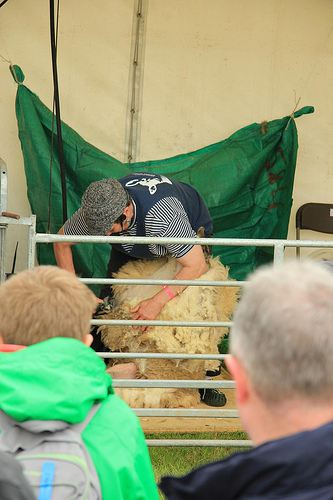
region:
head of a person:
[74, 183, 133, 245]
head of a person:
[195, 268, 331, 435]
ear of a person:
[217, 355, 246, 402]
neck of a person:
[229, 400, 329, 450]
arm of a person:
[139, 239, 203, 328]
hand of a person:
[125, 292, 168, 331]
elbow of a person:
[199, 256, 225, 278]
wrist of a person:
[150, 288, 173, 308]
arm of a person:
[48, 229, 99, 292]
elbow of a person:
[48, 229, 72, 259]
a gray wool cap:
[78, 177, 127, 234]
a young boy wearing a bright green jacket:
[0, 252, 153, 498]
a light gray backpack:
[0, 388, 110, 498]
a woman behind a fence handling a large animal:
[45, 170, 241, 407]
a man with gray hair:
[185, 258, 332, 498]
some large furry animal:
[91, 251, 237, 404]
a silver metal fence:
[0, 241, 330, 347]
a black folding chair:
[297, 201, 331, 256]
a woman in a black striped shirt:
[56, 174, 218, 273]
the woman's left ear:
[120, 208, 134, 216]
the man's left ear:
[218, 353, 249, 403]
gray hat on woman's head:
[80, 175, 127, 238]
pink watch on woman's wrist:
[159, 284, 177, 299]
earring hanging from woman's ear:
[124, 218, 132, 226]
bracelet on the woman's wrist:
[175, 274, 184, 302]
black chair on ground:
[293, 202, 331, 262]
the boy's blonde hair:
[0, 266, 91, 349]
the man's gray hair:
[233, 260, 331, 405]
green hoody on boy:
[5, 340, 113, 426]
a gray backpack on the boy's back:
[0, 399, 100, 498]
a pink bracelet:
[158, 285, 174, 300]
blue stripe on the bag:
[39, 460, 55, 498]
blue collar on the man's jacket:
[158, 423, 330, 498]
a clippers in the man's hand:
[94, 295, 116, 314]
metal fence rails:
[79, 277, 251, 446]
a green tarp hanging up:
[9, 64, 310, 268]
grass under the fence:
[146, 431, 245, 470]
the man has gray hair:
[223, 264, 331, 398]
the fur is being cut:
[94, 257, 231, 392]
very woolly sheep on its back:
[92, 253, 241, 405]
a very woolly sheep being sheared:
[90, 259, 235, 407]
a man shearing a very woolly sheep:
[52, 171, 227, 409]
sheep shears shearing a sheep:
[87, 287, 118, 315]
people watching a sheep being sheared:
[0, 261, 331, 496]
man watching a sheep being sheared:
[209, 254, 329, 463]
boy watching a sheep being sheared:
[0, 264, 159, 496]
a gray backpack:
[0, 417, 102, 496]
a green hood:
[0, 336, 113, 422]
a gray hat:
[80, 178, 126, 234]